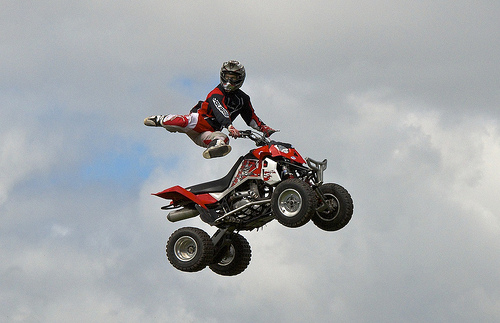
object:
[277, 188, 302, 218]
rim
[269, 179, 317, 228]
tire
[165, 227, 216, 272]
wheels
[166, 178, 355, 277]
4 wheeler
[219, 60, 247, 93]
helmet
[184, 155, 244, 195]
black seat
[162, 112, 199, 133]
leg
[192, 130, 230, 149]
leg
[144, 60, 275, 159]
man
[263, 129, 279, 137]
handle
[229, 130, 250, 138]
handle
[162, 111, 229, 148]
pants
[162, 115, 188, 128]
trim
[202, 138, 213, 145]
trim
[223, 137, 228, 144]
trim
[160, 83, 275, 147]
red trim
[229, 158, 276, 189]
decal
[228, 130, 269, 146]
bars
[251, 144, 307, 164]
red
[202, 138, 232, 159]
boot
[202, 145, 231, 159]
foot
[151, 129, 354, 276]
atv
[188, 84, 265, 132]
shirt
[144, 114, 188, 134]
kicking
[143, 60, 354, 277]
trick